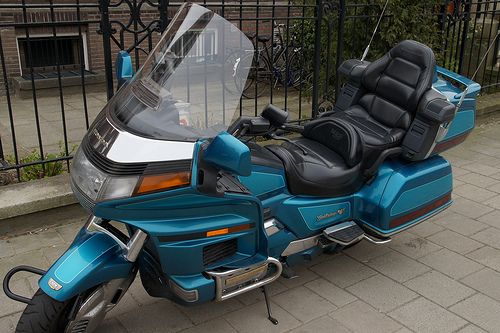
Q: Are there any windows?
A: Yes, there is a window.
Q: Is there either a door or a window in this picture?
A: Yes, there is a window.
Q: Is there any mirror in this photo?
A: Yes, there is a mirror.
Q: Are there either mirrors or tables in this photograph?
A: Yes, there is a mirror.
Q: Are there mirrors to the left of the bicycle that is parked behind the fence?
A: Yes, there is a mirror to the left of the bicycle.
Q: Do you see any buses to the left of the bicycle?
A: No, there is a mirror to the left of the bicycle.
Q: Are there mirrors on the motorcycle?
A: Yes, there is a mirror on the motorcycle.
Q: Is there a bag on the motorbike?
A: No, there is a mirror on the motorbike.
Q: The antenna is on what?
A: The antenna is on the motorbike.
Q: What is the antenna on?
A: The antenna is on the motorbike.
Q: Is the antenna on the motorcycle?
A: Yes, the antenna is on the motorcycle.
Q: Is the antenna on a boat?
A: No, the antenna is on the motorcycle.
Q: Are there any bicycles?
A: Yes, there is a bicycle.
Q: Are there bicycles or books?
A: Yes, there is a bicycle.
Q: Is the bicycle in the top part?
A: Yes, the bicycle is in the top of the image.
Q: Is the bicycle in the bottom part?
A: No, the bicycle is in the top of the image.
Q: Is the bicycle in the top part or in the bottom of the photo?
A: The bicycle is in the top of the image.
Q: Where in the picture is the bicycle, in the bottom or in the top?
A: The bicycle is in the top of the image.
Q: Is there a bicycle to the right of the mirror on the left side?
A: Yes, there is a bicycle to the right of the mirror.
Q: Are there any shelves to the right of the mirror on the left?
A: No, there is a bicycle to the right of the mirror.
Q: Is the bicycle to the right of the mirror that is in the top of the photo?
A: Yes, the bicycle is to the right of the mirror.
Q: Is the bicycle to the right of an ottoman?
A: No, the bicycle is to the right of the mirror.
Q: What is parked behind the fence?
A: The bicycle is parked behind the fence.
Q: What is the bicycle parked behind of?
A: The bicycle is parked behind the fence.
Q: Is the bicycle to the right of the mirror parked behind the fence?
A: Yes, the bicycle is parked behind the fence.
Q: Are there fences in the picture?
A: Yes, there is a fence.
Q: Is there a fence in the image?
A: Yes, there is a fence.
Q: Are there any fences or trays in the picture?
A: Yes, there is a fence.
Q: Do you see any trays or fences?
A: Yes, there is a fence.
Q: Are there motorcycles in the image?
A: Yes, there is a motorcycle.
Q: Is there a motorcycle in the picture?
A: Yes, there is a motorcycle.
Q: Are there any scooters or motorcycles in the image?
A: Yes, there is a motorcycle.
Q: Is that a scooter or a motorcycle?
A: That is a motorcycle.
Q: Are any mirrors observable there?
A: Yes, there is a mirror.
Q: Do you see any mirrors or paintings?
A: Yes, there is a mirror.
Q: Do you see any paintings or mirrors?
A: Yes, there is a mirror.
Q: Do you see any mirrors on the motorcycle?
A: Yes, there is a mirror on the motorcycle.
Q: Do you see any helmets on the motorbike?
A: No, there is a mirror on the motorbike.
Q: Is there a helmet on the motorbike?
A: No, there is a mirror on the motorbike.